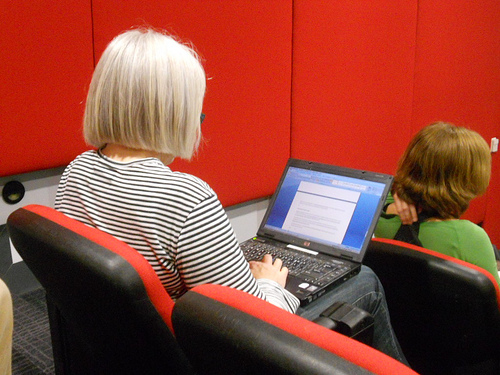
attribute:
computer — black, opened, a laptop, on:
[238, 156, 396, 308]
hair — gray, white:
[79, 25, 204, 159]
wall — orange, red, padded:
[0, 0, 499, 248]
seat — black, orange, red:
[7, 200, 183, 374]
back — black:
[365, 240, 500, 374]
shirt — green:
[374, 188, 499, 283]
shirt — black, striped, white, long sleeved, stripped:
[54, 143, 301, 313]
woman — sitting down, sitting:
[54, 26, 413, 367]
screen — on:
[268, 167, 386, 254]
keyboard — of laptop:
[238, 234, 352, 288]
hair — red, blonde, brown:
[390, 122, 494, 214]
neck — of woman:
[100, 141, 161, 165]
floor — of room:
[9, 287, 58, 374]